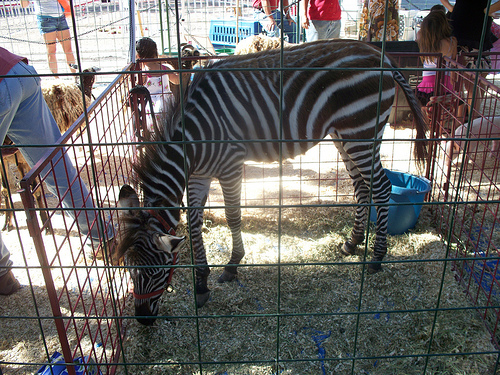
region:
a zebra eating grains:
[101, 58, 433, 310]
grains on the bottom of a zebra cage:
[196, 298, 276, 354]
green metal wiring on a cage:
[208, 249, 425, 365]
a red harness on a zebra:
[112, 251, 186, 301]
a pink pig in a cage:
[434, 112, 496, 177]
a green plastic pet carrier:
[190, 15, 257, 49]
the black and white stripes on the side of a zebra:
[227, 72, 325, 129]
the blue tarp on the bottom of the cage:
[305, 327, 339, 374]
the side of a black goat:
[51, 60, 101, 108]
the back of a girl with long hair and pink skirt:
[406, 6, 476, 107]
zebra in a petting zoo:
[91, 37, 434, 327]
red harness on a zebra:
[113, 200, 181, 303]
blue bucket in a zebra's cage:
[356, 157, 433, 238]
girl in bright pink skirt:
[412, 5, 459, 157]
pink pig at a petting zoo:
[440, 105, 499, 167]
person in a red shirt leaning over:
[0, 39, 131, 295]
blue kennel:
[206, 15, 277, 56]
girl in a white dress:
[129, 30, 185, 151]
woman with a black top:
[438, 1, 498, 109]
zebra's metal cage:
[12, 41, 499, 369]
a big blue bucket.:
[373, 163, 448, 238]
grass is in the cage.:
[241, 250, 408, 366]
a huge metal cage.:
[33, 39, 445, 364]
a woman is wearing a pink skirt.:
[418, 76, 447, 98]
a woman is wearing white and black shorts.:
[466, 50, 491, 74]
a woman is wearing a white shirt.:
[422, 52, 451, 77]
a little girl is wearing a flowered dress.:
[137, 74, 179, 129]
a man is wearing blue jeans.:
[2, 72, 50, 148]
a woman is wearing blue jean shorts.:
[27, 19, 77, 33]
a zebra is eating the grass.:
[74, 15, 484, 356]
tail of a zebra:
[385, 58, 439, 180]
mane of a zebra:
[117, 61, 199, 223]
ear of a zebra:
[154, 226, 192, 262]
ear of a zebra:
[111, 178, 145, 233]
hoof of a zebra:
[188, 273, 216, 315]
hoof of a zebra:
[210, 263, 245, 290]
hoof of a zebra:
[360, 255, 390, 283]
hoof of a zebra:
[331, 227, 361, 266]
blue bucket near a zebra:
[347, 161, 441, 246]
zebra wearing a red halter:
[105, 36, 450, 345]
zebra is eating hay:
[96, 129, 217, 336]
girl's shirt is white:
[135, 64, 175, 121]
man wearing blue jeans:
[4, 57, 139, 288]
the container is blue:
[356, 159, 437, 241]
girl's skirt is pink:
[418, 63, 461, 102]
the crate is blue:
[203, 14, 280, 65]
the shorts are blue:
[30, 9, 77, 43]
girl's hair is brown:
[399, 2, 453, 67]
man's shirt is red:
[306, 2, 346, 24]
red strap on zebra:
[109, 226, 177, 308]